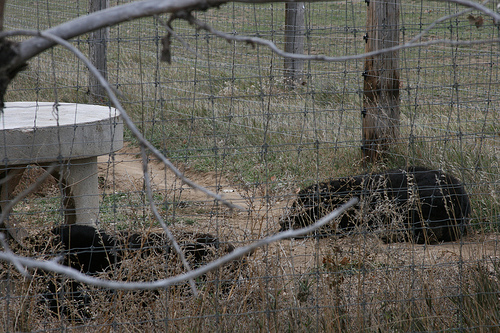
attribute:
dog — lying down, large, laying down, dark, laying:
[280, 164, 468, 248]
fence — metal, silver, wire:
[1, 0, 499, 333]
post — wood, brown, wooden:
[364, 2, 401, 163]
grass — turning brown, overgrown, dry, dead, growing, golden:
[0, 145, 499, 332]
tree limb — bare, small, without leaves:
[2, 2, 499, 291]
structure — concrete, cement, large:
[2, 100, 125, 265]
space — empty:
[6, 165, 71, 240]